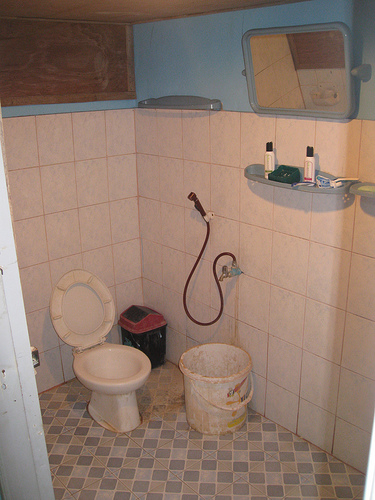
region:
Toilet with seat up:
[47, 267, 152, 435]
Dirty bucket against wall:
[177, 335, 259, 437]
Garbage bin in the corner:
[117, 299, 171, 368]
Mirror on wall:
[239, 21, 371, 122]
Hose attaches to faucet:
[181, 188, 241, 326]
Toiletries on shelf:
[242, 143, 351, 198]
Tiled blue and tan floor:
[49, 430, 280, 494]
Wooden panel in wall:
[0, 15, 136, 107]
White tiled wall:
[248, 205, 371, 447]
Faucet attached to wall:
[215, 258, 237, 291]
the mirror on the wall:
[235, 25, 364, 133]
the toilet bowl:
[32, 258, 161, 458]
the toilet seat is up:
[54, 260, 156, 437]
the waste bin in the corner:
[108, 288, 172, 360]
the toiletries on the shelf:
[234, 143, 368, 211]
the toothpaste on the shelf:
[316, 168, 348, 192]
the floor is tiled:
[159, 453, 244, 495]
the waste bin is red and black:
[112, 300, 181, 372]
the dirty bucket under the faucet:
[171, 330, 292, 466]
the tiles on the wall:
[259, 240, 374, 459]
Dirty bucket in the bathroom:
[179, 333, 282, 449]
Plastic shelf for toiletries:
[237, 118, 374, 202]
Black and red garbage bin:
[116, 286, 198, 394]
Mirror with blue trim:
[226, 33, 364, 123]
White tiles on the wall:
[274, 251, 362, 374]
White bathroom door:
[0, 254, 78, 489]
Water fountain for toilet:
[167, 175, 248, 328]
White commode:
[44, 248, 159, 446]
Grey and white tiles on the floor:
[125, 461, 224, 497]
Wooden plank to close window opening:
[0, 18, 142, 102]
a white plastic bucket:
[173, 331, 257, 452]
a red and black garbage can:
[119, 282, 162, 345]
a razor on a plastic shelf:
[328, 169, 364, 195]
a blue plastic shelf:
[245, 167, 358, 195]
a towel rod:
[126, 84, 227, 125]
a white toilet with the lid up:
[38, 243, 139, 434]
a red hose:
[177, 184, 230, 337]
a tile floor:
[94, 438, 290, 498]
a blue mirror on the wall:
[228, 15, 364, 141]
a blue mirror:
[223, 17, 362, 142]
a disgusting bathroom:
[2, 3, 370, 498]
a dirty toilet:
[40, 268, 168, 458]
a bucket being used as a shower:
[173, 332, 263, 445]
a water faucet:
[212, 260, 240, 284]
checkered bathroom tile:
[140, 432, 305, 487]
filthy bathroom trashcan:
[111, 295, 182, 382]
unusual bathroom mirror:
[235, 16, 374, 147]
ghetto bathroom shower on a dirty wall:
[174, 183, 250, 333]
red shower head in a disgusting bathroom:
[180, 187, 220, 240]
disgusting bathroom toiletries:
[241, 124, 360, 214]